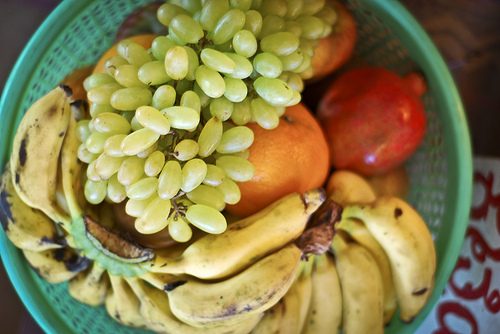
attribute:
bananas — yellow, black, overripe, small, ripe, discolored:
[153, 188, 438, 334]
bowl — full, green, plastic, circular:
[2, 2, 475, 333]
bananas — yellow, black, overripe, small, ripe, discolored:
[2, 84, 326, 333]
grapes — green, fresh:
[69, 2, 337, 245]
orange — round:
[315, 1, 358, 79]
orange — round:
[227, 106, 330, 221]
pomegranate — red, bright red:
[316, 68, 430, 176]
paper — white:
[411, 155, 499, 333]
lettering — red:
[431, 170, 499, 334]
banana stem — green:
[69, 215, 154, 285]